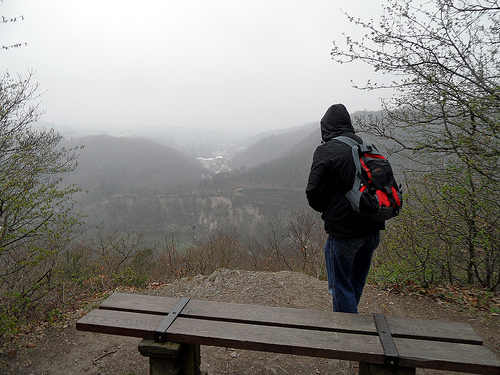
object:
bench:
[75, 290, 495, 374]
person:
[305, 103, 401, 314]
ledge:
[117, 268, 496, 330]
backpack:
[336, 135, 402, 219]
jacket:
[304, 103, 403, 235]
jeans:
[323, 229, 382, 313]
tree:
[0, 0, 124, 374]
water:
[192, 154, 226, 163]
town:
[198, 145, 241, 179]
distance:
[0, 0, 499, 271]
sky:
[0, 0, 491, 143]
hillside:
[199, 147, 325, 209]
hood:
[320, 103, 362, 139]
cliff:
[112, 267, 500, 327]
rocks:
[172, 271, 204, 283]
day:
[0, 0, 499, 375]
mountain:
[31, 132, 224, 198]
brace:
[153, 295, 189, 341]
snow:
[200, 192, 231, 210]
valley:
[138, 122, 310, 276]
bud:
[20, 13, 24, 22]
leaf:
[429, 274, 495, 288]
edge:
[213, 266, 299, 274]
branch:
[25, 69, 35, 89]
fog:
[0, 0, 499, 307]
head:
[320, 102, 353, 141]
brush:
[368, 196, 438, 291]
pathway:
[0, 268, 499, 375]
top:
[0, 0, 81, 155]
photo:
[1, 1, 498, 374]